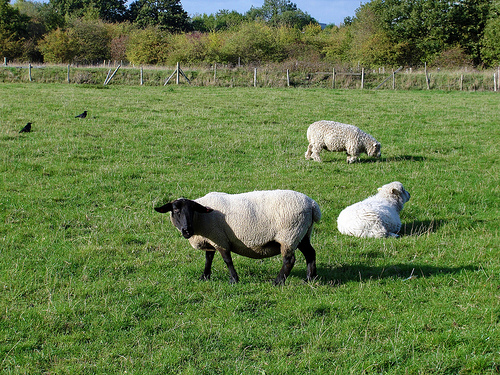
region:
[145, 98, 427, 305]
Three white haired sheep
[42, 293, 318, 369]
Green well maintained grass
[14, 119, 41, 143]
A small black bird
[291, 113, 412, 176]
A thick haired sheep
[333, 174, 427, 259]
A small beautiful sheep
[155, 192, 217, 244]
A black sheep head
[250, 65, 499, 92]
Dried up wooden poles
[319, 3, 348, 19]
A clear blue sky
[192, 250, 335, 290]
Black short strong legs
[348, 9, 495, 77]
A green bushy shrub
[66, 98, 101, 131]
Black bird standing in grass.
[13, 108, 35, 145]
Black bird standing in grass.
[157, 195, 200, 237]
Animal has black head.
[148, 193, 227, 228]
Animal has black ears.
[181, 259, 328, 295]
Animal has black legs.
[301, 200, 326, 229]
Animal has white tail.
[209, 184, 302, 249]
Animal has white wool.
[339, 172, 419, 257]
Animal is laying in grass.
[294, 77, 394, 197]
Animal is eating grass.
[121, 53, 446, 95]
Animals inside of fenced area.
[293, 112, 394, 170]
White sheep in grassy field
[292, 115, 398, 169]
Sheep grazing in field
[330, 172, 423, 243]
Sheep laying down in field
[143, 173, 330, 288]
Sheep standing in field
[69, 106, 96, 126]
Black bird in grassy field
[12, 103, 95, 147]
Two black birds in grass field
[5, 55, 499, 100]
Wooden and wire fence at edge of field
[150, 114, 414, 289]
Three sheep in a field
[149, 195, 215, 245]
Sheep looking to his left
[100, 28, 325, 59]
Wooded area beyond grassy field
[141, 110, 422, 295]
three sheeps on a field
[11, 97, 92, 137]
black crows on a field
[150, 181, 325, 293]
a sheep with black head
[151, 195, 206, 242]
head of sheep is black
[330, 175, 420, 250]
a sheep lying on the green grass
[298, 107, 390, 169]
a sheep eating grass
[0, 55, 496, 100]
a fence on side a field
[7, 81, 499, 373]
a field cover with grass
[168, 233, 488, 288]
shadow of sheep on grass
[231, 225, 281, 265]
belly of sheep is bulky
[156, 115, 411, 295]
Three sheep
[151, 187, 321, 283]
Sheep with a black face and legs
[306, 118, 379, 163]
White sheep eating grass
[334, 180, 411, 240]
White sheep resting and looking right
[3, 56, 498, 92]
Wooden and metal fence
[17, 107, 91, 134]
Two black birds on the ground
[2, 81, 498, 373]
Grassy field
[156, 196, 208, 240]
Head of a black sheep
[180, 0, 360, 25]
Bright clear blue sky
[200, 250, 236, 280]
Front legs of a black sheep